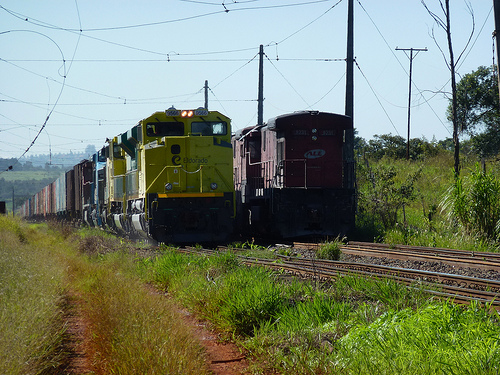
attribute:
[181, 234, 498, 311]
train tracks — part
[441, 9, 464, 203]
tree — part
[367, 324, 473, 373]
bushes — green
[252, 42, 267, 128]
power pole — part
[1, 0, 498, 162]
sky — blue